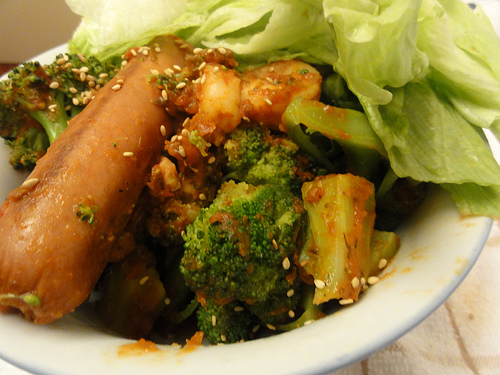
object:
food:
[0, 0, 499, 348]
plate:
[400, 244, 461, 317]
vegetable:
[197, 0, 499, 350]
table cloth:
[324, 221, 498, 374]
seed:
[313, 277, 325, 290]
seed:
[337, 299, 353, 305]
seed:
[351, 278, 358, 290]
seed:
[367, 276, 377, 286]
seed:
[379, 260, 386, 269]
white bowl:
[0, 38, 500, 373]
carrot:
[1, 32, 197, 325]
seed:
[120, 148, 135, 160]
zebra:
[187, 142, 307, 342]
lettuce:
[52, 0, 499, 221]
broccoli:
[165, 131, 313, 346]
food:
[0, 2, 500, 342]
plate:
[0, 337, 112, 375]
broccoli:
[175, 174, 308, 346]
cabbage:
[66, 1, 498, 214]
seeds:
[269, 235, 281, 253]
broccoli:
[183, 178, 306, 345]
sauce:
[163, 56, 297, 163]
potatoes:
[184, 61, 248, 142]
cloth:
[329, 223, 497, 373]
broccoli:
[184, 186, 301, 346]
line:
[445, 302, 477, 374]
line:
[359, 360, 370, 372]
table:
[0, 222, 498, 374]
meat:
[2, 30, 192, 329]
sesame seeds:
[109, 80, 123, 97]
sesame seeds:
[361, 271, 386, 286]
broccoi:
[190, 140, 315, 179]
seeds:
[151, 122, 176, 143]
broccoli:
[0, 47, 114, 163]